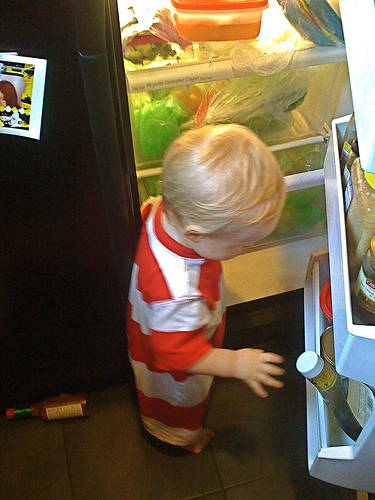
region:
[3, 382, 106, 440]
a bottle of Tabasco sauce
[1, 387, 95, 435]
bottle of Tabasco sauce on its side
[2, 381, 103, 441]
bottle of Tabasco sauce on the floor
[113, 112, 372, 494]
a child looking in the fridge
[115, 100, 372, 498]
a young child looking in the refrigerator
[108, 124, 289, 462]
a young child wearing stripes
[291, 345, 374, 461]
a bottle on the refrigerator shelf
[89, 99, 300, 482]
young child with an outstretched hand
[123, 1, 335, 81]
things on the top shelf of a refrigerator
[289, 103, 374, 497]
side door of an opened refrigerator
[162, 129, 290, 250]
the boy has blond hair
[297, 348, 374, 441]
a bottle is in the fridge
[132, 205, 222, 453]
the shirt is red and white in color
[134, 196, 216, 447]
the shirt has red and white stripes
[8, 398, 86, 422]
a bottle is on the floor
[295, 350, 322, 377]
the cap on bottle is white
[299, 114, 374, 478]
the fridge shelves are white in color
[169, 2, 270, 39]
the container is made of plastic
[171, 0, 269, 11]
the lid of container is red in color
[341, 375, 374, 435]
the bottle has a label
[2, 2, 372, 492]
open door of refrigerator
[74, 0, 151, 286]
handle on freezer door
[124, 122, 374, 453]
child looking at fridge door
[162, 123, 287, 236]
blonde hair on child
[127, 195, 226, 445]
orange and white shirt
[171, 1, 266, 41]
plastic container with lid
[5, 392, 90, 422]
bottle laying on floor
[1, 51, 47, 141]
picture on black door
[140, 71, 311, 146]
food in plastic bags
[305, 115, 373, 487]
bottles in fridge door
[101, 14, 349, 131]
this is a refregirator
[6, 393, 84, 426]
a bottle of sauce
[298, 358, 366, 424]
a bottle of vineger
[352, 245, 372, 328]
a tin of jam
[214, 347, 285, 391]
the hand of the child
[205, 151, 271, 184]
the hair of the child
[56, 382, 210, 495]
that is a tile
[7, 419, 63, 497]
that is a tile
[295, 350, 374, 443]
A bottle of dressing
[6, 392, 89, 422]
A bottle of hot sauce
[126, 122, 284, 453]
A young blonde child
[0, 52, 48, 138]
A picture on the fridge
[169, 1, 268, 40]
A plastic container that holds food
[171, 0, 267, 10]
The red top of the container that holds food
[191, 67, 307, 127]
A bag holding an unidentifiable vegetable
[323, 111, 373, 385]
The top shelf of the fridge door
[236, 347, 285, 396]
The right hand of a child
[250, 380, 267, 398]
The pinky finger of a child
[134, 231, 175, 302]
red stripe on shirt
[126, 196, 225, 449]
shirt is worn by child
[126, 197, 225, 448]
shirt is red and white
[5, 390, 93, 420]
bottle sits on ground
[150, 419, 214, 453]
foot belongs to child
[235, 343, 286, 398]
hand belongs to child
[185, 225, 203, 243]
ear belongs to child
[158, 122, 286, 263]
head belongs to child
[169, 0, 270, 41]
container sits in fridge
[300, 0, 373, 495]
fridge door is open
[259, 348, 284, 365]
finger belongs to human